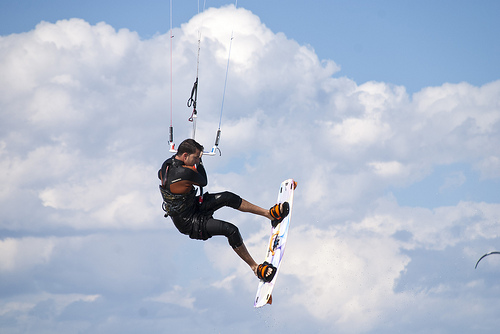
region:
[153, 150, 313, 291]
the man is in the air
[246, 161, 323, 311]
the surfboard is white in color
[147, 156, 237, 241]
the clothing is black in color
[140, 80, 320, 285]
the man is holding ropes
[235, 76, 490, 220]
the sky is cloudy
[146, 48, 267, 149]
there are three ropes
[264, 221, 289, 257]
there is graffiti on the board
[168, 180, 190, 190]
the inner shirt is orange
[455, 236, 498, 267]
there is a parachute in the background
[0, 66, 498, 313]
the photo was taken in the day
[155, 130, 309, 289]
this is a man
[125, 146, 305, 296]
the man is sky diving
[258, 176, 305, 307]
this is a skateboard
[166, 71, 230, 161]
the man is holding ropes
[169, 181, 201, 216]
the man has black costumes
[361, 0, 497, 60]
the sky is blue in color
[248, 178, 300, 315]
the skateboard is white in color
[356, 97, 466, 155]
the clouds are white in color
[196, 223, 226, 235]
the costume is tight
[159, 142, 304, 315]
Man is in the air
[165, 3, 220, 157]
man holds onto bar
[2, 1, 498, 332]
sky is blue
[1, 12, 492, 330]
clouds are behind man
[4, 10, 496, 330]
clouds are in sky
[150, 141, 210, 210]
man wears safety harness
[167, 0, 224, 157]
ropes attatched to bar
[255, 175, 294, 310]
man stands on board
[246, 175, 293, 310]
board is strapped to feet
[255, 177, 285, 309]
board is white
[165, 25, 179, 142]
this is the left string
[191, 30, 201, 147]
this is the center string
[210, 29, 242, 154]
this is the right string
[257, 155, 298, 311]
this is a water ski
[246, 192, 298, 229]
this is the left foot strap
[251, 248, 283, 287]
this is the right foot strap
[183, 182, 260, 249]
these are black pants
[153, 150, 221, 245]
this is a harness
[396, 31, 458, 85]
this is the sky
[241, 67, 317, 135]
this is a cloud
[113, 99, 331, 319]
Surfer parasailing.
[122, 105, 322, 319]
Parasailing in the air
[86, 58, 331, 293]
White clouds in the blue sky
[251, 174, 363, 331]
White surf board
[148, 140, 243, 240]
Man parasailing in the water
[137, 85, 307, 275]
Holding on to the harness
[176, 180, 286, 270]
Black shorts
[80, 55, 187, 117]
Lots of clouds in the sky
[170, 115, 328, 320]
Man in the air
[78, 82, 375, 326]
Nice summer day for parasailing